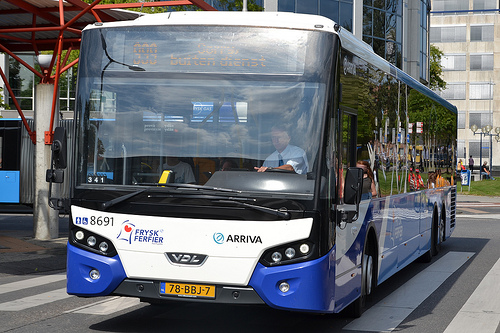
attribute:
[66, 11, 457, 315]
bus — blue, white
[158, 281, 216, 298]
license plate — yellow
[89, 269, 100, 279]
headlight — circular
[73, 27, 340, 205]
windsheild — reflective, large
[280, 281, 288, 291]
headlight — round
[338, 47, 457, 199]
side windows — reflective